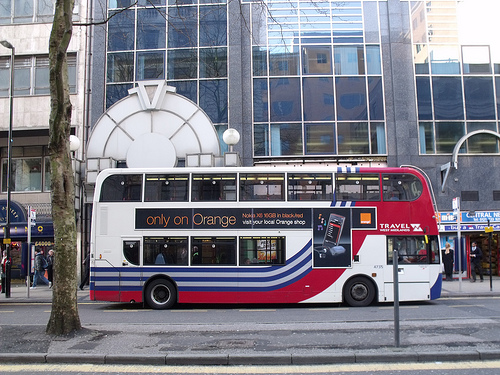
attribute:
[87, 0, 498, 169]
building — gray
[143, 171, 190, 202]
window — upper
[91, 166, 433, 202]
level — upper 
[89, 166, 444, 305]
bus — double decker, red, white, blue, tinted